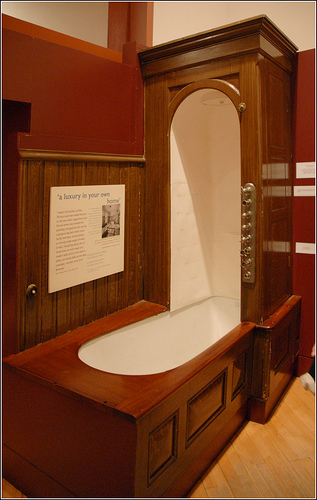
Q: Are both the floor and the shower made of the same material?
A: Yes, both the floor and the shower are made of wood.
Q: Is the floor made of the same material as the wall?
A: Yes, both the floor and the wall are made of wood.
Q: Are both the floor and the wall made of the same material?
A: Yes, both the floor and the wall are made of wood.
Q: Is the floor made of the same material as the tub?
A: Yes, both the floor and the tub are made of wood.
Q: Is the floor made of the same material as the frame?
A: Yes, both the floor and the frame are made of wood.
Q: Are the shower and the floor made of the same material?
A: Yes, both the shower and the floor are made of wood.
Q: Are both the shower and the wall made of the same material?
A: Yes, both the shower and the wall are made of wood.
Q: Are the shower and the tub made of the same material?
A: Yes, both the shower and the tub are made of wood.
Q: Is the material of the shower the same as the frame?
A: Yes, both the shower and the frame are made of wood.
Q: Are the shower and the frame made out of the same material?
A: Yes, both the shower and the frame are made of wood.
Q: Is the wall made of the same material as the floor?
A: Yes, both the wall and the floor are made of wood.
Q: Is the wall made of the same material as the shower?
A: Yes, both the wall and the shower are made of wood.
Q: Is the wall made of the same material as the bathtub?
A: Yes, both the wall and the bathtub are made of wood.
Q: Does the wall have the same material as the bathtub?
A: Yes, both the wall and the bathtub are made of wood.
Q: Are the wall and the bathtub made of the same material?
A: Yes, both the wall and the bathtub are made of wood.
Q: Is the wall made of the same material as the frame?
A: Yes, both the wall and the frame are made of wood.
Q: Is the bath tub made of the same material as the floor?
A: Yes, both the bath tub and the floor are made of wood.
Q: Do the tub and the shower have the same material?
A: Yes, both the tub and the shower are made of wood.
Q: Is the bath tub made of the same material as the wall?
A: Yes, both the bath tub and the wall are made of wood.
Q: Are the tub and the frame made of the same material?
A: Yes, both the tub and the frame are made of wood.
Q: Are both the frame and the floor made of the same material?
A: Yes, both the frame and the floor are made of wood.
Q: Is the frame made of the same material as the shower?
A: Yes, both the frame and the shower are made of wood.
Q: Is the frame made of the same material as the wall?
A: Yes, both the frame and the wall are made of wood.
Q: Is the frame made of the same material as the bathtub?
A: Yes, both the frame and the bathtub are made of wood.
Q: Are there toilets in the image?
A: No, there are no toilets.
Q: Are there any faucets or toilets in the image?
A: No, there are no toilets or faucets.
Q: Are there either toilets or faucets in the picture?
A: No, there are no toilets or faucets.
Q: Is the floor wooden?
A: Yes, the floor is wooden.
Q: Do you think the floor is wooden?
A: Yes, the floor is wooden.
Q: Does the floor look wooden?
A: Yes, the floor is wooden.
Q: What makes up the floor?
A: The floor is made of wood.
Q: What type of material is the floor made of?
A: The floor is made of wood.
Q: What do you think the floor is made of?
A: The floor is made of wood.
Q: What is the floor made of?
A: The floor is made of wood.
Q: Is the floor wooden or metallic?
A: The floor is wooden.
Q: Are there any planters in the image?
A: No, there are no planters.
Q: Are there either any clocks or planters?
A: No, there are no planters or clocks.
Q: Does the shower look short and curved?
A: No, the shower is curved but tall.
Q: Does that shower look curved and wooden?
A: Yes, the shower is curved and wooden.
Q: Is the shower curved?
A: Yes, the shower is curved.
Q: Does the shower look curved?
A: Yes, the shower is curved.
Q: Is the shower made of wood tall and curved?
A: Yes, the shower is tall and curved.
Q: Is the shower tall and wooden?
A: Yes, the shower is tall and wooden.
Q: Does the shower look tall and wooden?
A: Yes, the shower is tall and wooden.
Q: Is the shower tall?
A: Yes, the shower is tall.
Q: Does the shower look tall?
A: Yes, the shower is tall.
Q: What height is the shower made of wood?
A: The shower is tall.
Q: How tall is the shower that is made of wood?
A: The shower is tall.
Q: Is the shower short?
A: No, the shower is tall.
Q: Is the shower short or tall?
A: The shower is tall.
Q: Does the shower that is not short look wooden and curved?
A: Yes, the shower is wooden and curved.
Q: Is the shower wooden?
A: Yes, the shower is wooden.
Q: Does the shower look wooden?
A: Yes, the shower is wooden.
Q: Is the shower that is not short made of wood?
A: Yes, the shower is made of wood.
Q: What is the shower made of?
A: The shower is made of wood.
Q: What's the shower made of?
A: The shower is made of wood.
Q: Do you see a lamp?
A: No, there are no lamps.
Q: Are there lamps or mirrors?
A: No, there are no lamps or mirrors.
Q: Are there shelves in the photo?
A: No, there are no shelves.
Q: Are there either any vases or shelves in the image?
A: No, there are no shelves or vases.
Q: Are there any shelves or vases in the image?
A: No, there are no shelves or vases.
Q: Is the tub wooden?
A: Yes, the tub is wooden.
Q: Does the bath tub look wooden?
A: Yes, the bath tub is wooden.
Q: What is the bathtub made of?
A: The bathtub is made of wood.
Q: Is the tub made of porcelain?
A: No, the tub is made of wood.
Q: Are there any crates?
A: No, there are no crates.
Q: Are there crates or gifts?
A: No, there are no crates or gifts.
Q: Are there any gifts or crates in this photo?
A: No, there are no crates or gifts.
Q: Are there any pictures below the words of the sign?
A: Yes, there is a picture below the words.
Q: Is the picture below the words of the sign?
A: Yes, the picture is below the words.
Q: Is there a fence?
A: No, there are no fences.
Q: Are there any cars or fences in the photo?
A: No, there are no fences or cars.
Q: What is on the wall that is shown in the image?
A: The sign is on the wall.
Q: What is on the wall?
A: The sign is on the wall.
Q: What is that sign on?
A: The sign is on the wall.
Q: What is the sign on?
A: The sign is on the wall.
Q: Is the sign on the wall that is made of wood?
A: Yes, the sign is on the wall.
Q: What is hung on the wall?
A: The sign is hung on the wall.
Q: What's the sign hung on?
A: The sign is hung on the wall.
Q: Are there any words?
A: Yes, there are words.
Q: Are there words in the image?
A: Yes, there are words.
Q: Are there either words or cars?
A: Yes, there are words.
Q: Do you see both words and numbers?
A: No, there are words but no numbers.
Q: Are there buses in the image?
A: No, there are no buses.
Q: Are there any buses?
A: No, there are no buses.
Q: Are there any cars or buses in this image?
A: No, there are no buses or cars.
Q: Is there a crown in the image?
A: No, there are no crowns.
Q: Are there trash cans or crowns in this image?
A: No, there are no crowns or trash cans.